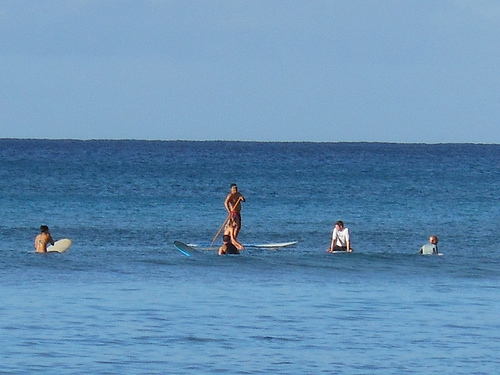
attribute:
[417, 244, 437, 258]
shirt — blue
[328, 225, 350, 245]
shirt — white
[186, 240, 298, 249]
board — white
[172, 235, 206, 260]
surfboard — blue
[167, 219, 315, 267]
surfboard — white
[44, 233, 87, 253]
surfboard — white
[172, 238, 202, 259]
sport board — blue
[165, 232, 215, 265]
surfboard — black, blue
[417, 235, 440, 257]
person — bald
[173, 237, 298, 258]
surfboard — blue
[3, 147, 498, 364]
surfboard — white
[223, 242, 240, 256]
top — black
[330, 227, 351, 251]
shirt — white